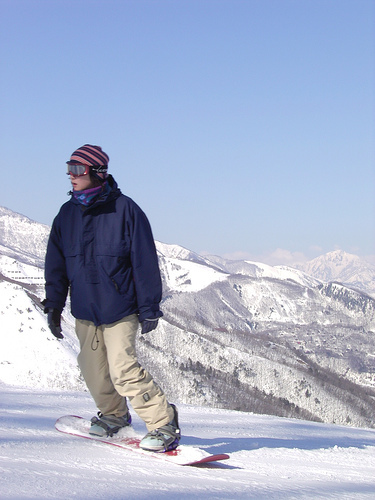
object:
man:
[43, 143, 182, 451]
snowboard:
[55, 413, 232, 466]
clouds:
[188, 197, 337, 239]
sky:
[171, 12, 368, 238]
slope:
[0, 384, 373, 496]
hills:
[0, 202, 375, 422]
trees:
[179, 363, 186, 371]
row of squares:
[4, 268, 53, 289]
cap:
[64, 144, 109, 179]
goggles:
[65, 161, 99, 178]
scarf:
[72, 179, 111, 207]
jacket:
[43, 174, 164, 350]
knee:
[107, 356, 138, 389]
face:
[69, 160, 95, 192]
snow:
[65, 456, 329, 496]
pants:
[74, 313, 176, 431]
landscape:
[12, 203, 372, 391]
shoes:
[138, 404, 182, 451]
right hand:
[48, 319, 65, 339]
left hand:
[141, 316, 159, 334]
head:
[65, 144, 110, 193]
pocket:
[96, 244, 126, 275]